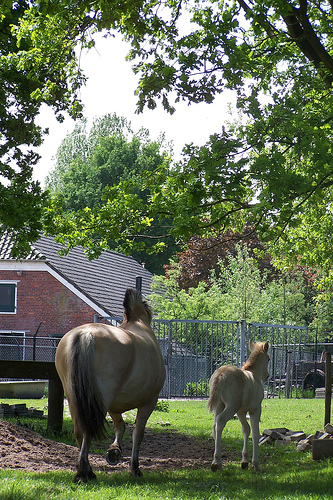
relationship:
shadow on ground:
[39, 458, 318, 498] [2, 397, 328, 498]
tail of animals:
[65, 330, 109, 437] [54, 288, 167, 488]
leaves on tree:
[143, 64, 184, 100] [256, 15, 328, 95]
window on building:
[2, 280, 16, 316] [1, 221, 173, 372]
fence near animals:
[4, 322, 329, 401] [24, 266, 279, 498]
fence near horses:
[196, 311, 227, 362] [51, 288, 273, 467]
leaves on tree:
[290, 114, 319, 160] [103, 0, 332, 326]